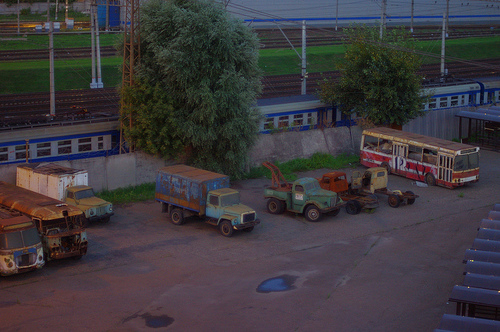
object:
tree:
[313, 21, 438, 142]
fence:
[0, 106, 457, 195]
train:
[0, 77, 500, 166]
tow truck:
[262, 160, 344, 222]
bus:
[0, 207, 46, 279]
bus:
[0, 181, 89, 262]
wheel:
[304, 205, 322, 222]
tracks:
[0, 24, 497, 61]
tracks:
[0, 57, 500, 132]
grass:
[5, 33, 495, 88]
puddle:
[138, 310, 174, 328]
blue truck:
[154, 163, 261, 236]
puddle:
[255, 274, 297, 293]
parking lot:
[3, 150, 497, 330]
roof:
[455, 109, 499, 123]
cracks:
[326, 233, 379, 299]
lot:
[2, 140, 498, 330]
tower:
[116, 1, 147, 156]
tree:
[118, 1, 265, 181]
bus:
[359, 127, 481, 189]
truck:
[316, 171, 380, 215]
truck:
[349, 166, 420, 208]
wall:
[43, 153, 293, 189]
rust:
[160, 164, 227, 181]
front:
[206, 188, 261, 237]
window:
[279, 116, 290, 128]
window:
[78, 137, 92, 152]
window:
[57, 140, 73, 155]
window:
[15, 145, 31, 159]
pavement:
[3, 202, 444, 331]